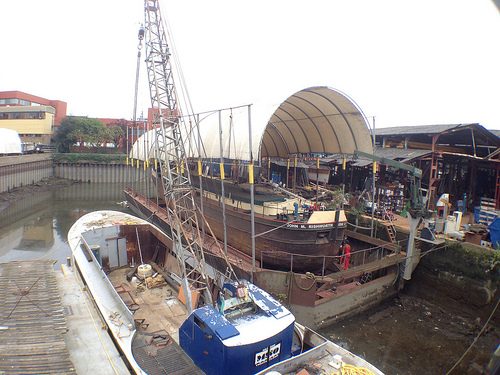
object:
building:
[0, 105, 54, 151]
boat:
[150, 163, 348, 273]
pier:
[1, 259, 82, 375]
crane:
[131, 1, 228, 307]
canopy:
[128, 84, 375, 160]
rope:
[335, 363, 372, 375]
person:
[342, 238, 352, 270]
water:
[17, 191, 61, 226]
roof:
[366, 122, 499, 134]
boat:
[66, 209, 384, 374]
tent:
[128, 82, 377, 163]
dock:
[125, 185, 442, 330]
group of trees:
[50, 115, 126, 160]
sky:
[370, 2, 499, 93]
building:
[1, 90, 180, 155]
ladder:
[382, 222, 401, 247]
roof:
[128, 83, 375, 164]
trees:
[52, 116, 126, 154]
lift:
[357, 150, 422, 282]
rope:
[252, 218, 297, 241]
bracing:
[125, 102, 259, 264]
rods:
[145, 58, 215, 313]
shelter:
[371, 122, 499, 224]